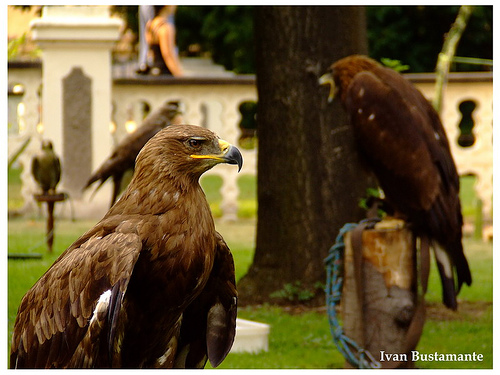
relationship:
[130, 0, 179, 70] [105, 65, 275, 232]
woman leaning against a wall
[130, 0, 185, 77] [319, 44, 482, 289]
woman walking by bird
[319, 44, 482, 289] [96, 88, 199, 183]
bird walking by bird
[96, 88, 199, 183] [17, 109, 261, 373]
bird walking by bird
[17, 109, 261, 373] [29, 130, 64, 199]
bird walking by bird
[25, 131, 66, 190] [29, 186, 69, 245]
bird on a stand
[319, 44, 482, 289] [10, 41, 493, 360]
bird in a pen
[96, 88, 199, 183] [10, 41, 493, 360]
bird in a pen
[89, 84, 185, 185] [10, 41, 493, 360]
bird in a pen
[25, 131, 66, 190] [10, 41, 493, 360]
bird in a pen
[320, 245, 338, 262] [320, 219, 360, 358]
knot in cord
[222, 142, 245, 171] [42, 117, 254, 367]
beak on bird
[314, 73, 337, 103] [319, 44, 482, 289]
mouth on bird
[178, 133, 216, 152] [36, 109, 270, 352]
eye on bird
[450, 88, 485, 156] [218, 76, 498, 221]
design on fence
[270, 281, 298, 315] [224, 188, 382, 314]
branch at bottom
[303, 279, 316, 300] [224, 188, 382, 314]
branch at bottom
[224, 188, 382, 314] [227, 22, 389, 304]
bottom of tree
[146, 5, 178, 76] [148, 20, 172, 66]
girl wearing shirt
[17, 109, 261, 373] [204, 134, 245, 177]
bird with beak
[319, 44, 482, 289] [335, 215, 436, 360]
bird sitting on a stump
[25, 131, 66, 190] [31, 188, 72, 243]
bird sitting on a stand